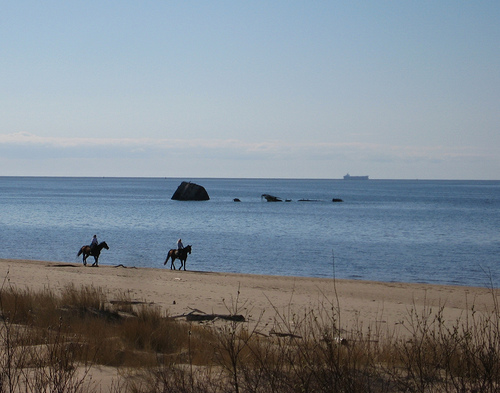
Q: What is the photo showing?
A: It is showing a beach.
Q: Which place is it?
A: It is a beach.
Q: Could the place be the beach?
A: Yes, it is the beach.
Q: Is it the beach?
A: Yes, it is the beach.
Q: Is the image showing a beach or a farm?
A: It is showing a beach.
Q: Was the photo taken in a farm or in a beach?
A: It was taken at a beach.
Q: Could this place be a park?
A: No, it is a beach.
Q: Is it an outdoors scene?
A: Yes, it is outdoors.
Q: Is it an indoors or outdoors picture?
A: It is outdoors.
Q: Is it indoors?
A: No, it is outdoors.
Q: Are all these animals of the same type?
A: Yes, all the animals are horses.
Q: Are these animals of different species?
A: No, all the animals are horses.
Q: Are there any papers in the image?
A: No, there are no papers.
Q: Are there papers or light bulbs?
A: No, there are no papers or light bulbs.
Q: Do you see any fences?
A: No, there are no fences.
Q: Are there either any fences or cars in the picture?
A: No, there are no fences or cars.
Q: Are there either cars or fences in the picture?
A: No, there are no fences or cars.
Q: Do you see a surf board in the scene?
A: No, there are no surfboards.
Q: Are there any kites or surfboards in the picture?
A: No, there are no surfboards or kites.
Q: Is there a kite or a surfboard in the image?
A: No, there are no surfboards or kites.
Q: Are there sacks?
A: No, there are no sacks.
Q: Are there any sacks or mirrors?
A: No, there are no sacks or mirrors.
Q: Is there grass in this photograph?
A: Yes, there is grass.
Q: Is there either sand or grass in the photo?
A: Yes, there is grass.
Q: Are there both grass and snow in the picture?
A: No, there is grass but no snow.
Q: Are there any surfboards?
A: No, there are no surfboards.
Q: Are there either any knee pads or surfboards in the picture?
A: No, there are no surfboards or knee pads.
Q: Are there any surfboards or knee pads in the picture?
A: No, there are no surfboards or knee pads.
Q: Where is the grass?
A: The grass is on the beach.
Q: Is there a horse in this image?
A: Yes, there are horses.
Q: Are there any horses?
A: Yes, there are horses.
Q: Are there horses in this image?
A: Yes, there are horses.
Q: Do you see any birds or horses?
A: Yes, there are horses.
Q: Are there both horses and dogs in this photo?
A: No, there are horses but no dogs.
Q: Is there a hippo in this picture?
A: No, there are no hippoes.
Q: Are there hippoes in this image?
A: No, there are no hippoes.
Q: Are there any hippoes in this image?
A: No, there are no hippoes.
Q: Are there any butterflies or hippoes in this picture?
A: No, there are no hippoes or butterflies.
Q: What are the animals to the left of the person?
A: The animals are horses.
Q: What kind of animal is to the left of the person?
A: The animals are horses.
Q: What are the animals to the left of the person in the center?
A: The animals are horses.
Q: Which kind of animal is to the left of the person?
A: The animals are horses.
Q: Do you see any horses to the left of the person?
A: Yes, there are horses to the left of the person.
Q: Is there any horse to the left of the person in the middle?
A: Yes, there are horses to the left of the person.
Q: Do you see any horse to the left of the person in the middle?
A: Yes, there are horses to the left of the person.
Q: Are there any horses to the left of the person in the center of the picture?
A: Yes, there are horses to the left of the person.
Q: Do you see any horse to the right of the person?
A: No, the horses are to the left of the person.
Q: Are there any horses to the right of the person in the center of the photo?
A: No, the horses are to the left of the person.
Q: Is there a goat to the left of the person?
A: No, there are horses to the left of the person.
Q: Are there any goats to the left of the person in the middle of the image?
A: No, there are horses to the left of the person.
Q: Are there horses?
A: Yes, there is a horse.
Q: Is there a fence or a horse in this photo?
A: Yes, there is a horse.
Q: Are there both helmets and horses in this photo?
A: No, there is a horse but no helmets.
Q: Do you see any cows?
A: No, there are no cows.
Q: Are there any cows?
A: No, there are no cows.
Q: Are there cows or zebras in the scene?
A: No, there are no cows or zebras.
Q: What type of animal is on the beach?
A: The animal is a horse.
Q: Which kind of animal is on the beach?
A: The animal is a horse.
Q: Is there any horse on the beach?
A: Yes, there is a horse on the beach.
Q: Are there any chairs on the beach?
A: No, there is a horse on the beach.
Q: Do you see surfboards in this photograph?
A: No, there are no surfboards.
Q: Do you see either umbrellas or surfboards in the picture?
A: No, there are no surfboards or umbrellas.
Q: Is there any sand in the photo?
A: Yes, there is sand.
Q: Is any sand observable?
A: Yes, there is sand.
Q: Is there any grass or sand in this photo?
A: Yes, there is sand.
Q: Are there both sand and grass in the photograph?
A: Yes, there are both sand and grass.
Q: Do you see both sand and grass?
A: Yes, there are both sand and grass.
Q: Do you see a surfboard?
A: No, there are no surfboards.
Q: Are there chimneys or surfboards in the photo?
A: No, there are no surfboards or chimneys.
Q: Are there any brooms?
A: No, there are no brooms.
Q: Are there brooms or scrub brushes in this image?
A: No, there are no brooms or scrub brushes.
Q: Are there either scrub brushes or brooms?
A: No, there are no brooms or scrub brushes.